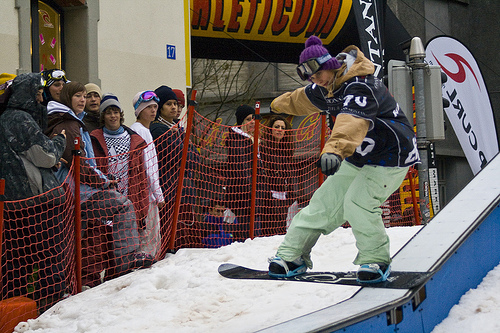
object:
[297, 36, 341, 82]
bonnet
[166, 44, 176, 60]
17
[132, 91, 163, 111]
goggles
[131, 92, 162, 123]
head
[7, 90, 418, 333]
fence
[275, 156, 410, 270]
pants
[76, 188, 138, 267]
pants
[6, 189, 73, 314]
pants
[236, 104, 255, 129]
hat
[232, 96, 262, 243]
person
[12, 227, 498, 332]
snow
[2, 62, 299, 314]
audience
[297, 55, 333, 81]
goggle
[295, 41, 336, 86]
head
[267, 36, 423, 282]
guy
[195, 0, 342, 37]
sign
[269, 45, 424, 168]
jacket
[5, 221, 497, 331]
ground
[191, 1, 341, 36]
red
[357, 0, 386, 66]
sign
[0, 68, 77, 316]
spectator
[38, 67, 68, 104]
spectator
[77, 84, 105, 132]
spectator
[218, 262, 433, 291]
skateboarder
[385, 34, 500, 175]
flag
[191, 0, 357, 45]
banner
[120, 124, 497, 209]
building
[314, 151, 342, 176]
glove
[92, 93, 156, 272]
people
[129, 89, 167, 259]
people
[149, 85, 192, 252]
people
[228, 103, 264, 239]
people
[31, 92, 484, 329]
ramp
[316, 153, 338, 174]
hand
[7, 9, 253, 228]
wall